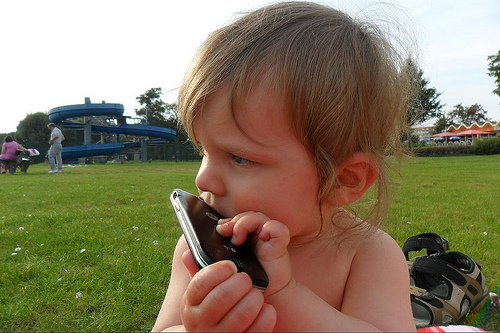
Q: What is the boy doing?
A: Biting a cell phone.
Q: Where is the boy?
A: On the grass.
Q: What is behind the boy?
A: A blue slide.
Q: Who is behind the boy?
A: A man.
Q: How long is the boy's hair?
A: The boy's hair is long.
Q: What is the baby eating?
A: A smartphone.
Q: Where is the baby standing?
A: Field of grass.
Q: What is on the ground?
A: A shoe.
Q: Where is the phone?
A: In baby's mouth.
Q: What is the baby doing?
A: Teething on a phone.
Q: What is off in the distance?
A: A blue water slide.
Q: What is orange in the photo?
A: Merry go round.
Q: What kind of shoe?
A: A sandal.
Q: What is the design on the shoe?
A: Camouflage.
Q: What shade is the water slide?
A: Blue.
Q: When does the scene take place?
A: During the daytime.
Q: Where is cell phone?
A: In toddler's hands.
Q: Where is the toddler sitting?
A: On the grass.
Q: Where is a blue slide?
A: In the distance.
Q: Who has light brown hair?
A: The toddler.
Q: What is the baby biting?
A: Cell phone.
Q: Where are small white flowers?
A: In the grass.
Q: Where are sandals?
A: Behind the toddler.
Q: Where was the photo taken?
A: At the park.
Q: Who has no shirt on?
A: Toddler.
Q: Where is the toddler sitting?
A: In the park.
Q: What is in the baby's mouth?
A: Cell phone.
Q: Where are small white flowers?
A: In the grass.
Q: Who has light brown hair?
A: The child.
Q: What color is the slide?
A: Blue.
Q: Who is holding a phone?
A: A baby.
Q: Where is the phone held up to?
A: The baby's mouth.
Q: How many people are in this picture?
A: Three.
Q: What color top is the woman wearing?
A: Pink.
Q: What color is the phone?
A: Black.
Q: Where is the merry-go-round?
A: In the background to the right.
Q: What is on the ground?
A: Grass.